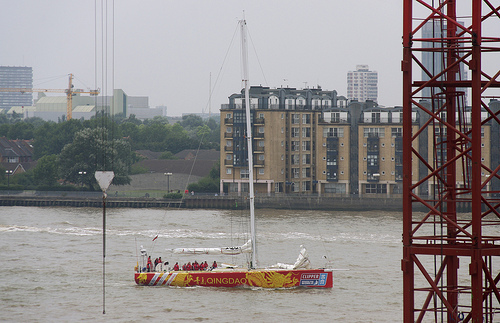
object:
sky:
[0, 0, 499, 113]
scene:
[1, 0, 500, 322]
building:
[216, 85, 500, 198]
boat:
[133, 269, 333, 289]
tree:
[53, 124, 131, 195]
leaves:
[161, 191, 184, 198]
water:
[0, 202, 499, 323]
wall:
[217, 109, 269, 180]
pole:
[240, 21, 257, 270]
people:
[173, 260, 179, 270]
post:
[402, 0, 412, 322]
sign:
[94, 170, 117, 198]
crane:
[1, 73, 104, 119]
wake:
[1, 223, 406, 245]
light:
[164, 171, 173, 175]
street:
[0, 189, 499, 198]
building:
[345, 60, 379, 101]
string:
[162, 24, 243, 247]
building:
[420, 16, 469, 105]